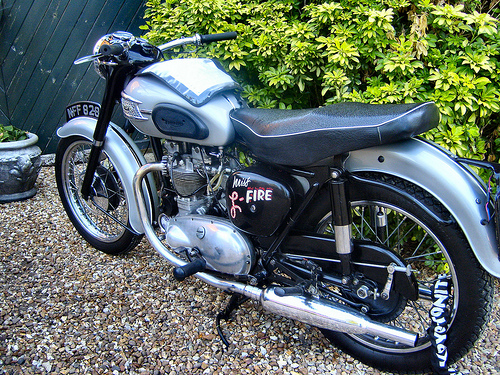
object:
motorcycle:
[64, 25, 499, 374]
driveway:
[0, 158, 499, 375]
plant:
[0, 130, 32, 147]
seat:
[229, 102, 443, 165]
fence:
[0, 0, 155, 154]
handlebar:
[155, 30, 235, 54]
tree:
[141, 0, 500, 186]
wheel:
[50, 133, 152, 256]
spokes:
[70, 148, 126, 237]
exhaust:
[254, 273, 403, 359]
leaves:
[297, 84, 305, 92]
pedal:
[177, 251, 212, 284]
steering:
[71, 21, 239, 61]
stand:
[221, 291, 244, 318]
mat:
[136, 59, 241, 106]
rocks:
[0, 199, 500, 374]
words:
[430, 278, 459, 367]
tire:
[282, 183, 500, 374]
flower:
[0, 122, 25, 143]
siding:
[0, 0, 29, 65]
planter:
[1, 128, 43, 201]